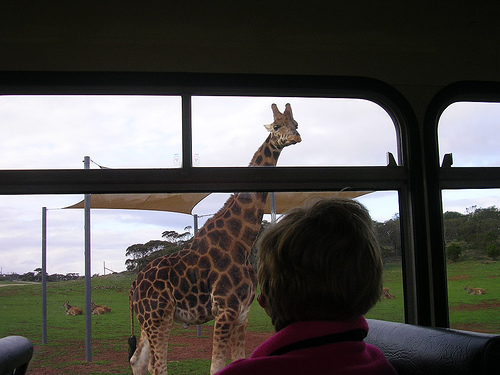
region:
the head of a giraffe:
[258, 97, 310, 151]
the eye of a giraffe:
[270, 121, 283, 132]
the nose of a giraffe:
[287, 127, 305, 139]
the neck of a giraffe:
[200, 137, 285, 239]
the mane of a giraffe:
[188, 137, 267, 238]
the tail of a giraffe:
[124, 277, 140, 367]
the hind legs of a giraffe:
[144, 305, 172, 373]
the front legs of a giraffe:
[201, 310, 249, 373]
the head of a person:
[243, 182, 390, 341]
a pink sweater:
[206, 310, 389, 372]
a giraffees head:
[241, 100, 323, 152]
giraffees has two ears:
[271, 103, 301, 115]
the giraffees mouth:
[278, 130, 310, 145]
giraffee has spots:
[151, 260, 205, 282]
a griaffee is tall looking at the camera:
[102, 100, 330, 372]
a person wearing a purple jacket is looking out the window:
[222, 195, 409, 374]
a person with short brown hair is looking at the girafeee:
[241, 187, 390, 329]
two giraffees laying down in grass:
[59, 292, 116, 323]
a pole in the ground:
[80, 155, 96, 363]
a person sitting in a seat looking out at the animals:
[352, 318, 496, 373]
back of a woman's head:
[248, 205, 381, 371]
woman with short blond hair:
[254, 203, 396, 373]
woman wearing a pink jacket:
[255, 206, 362, 360]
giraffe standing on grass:
[122, 106, 273, 370]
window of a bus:
[2, 65, 421, 322]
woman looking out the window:
[237, 189, 418, 371]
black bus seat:
[373, 315, 463, 372]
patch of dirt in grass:
[42, 330, 127, 373]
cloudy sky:
[22, 107, 122, 145]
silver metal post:
[82, 150, 105, 369]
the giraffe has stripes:
[77, 104, 298, 366]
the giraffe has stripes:
[135, 177, 292, 337]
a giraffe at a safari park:
[131, 103, 300, 374]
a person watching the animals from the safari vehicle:
[212, 196, 383, 374]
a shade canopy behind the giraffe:
[41, 155, 211, 216]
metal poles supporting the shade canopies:
[37, 205, 51, 345]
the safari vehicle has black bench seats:
[366, 316, 498, 374]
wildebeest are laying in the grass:
[61, 299, 82, 316]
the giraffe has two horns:
[271, 101, 293, 119]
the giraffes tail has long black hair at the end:
[128, 294, 137, 365]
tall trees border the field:
[444, 204, 499, 262]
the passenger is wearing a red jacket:
[212, 316, 394, 373]